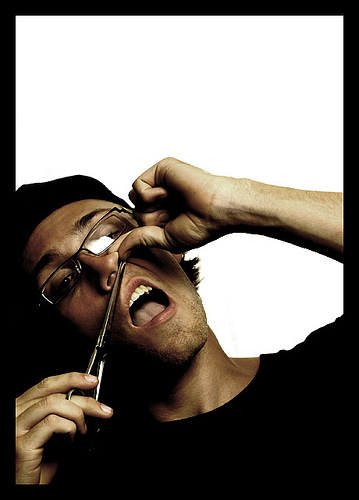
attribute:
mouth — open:
[115, 263, 156, 318]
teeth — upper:
[119, 282, 147, 303]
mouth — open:
[119, 273, 176, 329]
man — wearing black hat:
[16, 157, 344, 483]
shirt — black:
[48, 315, 344, 490]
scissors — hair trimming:
[76, 261, 124, 413]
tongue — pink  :
[138, 298, 169, 320]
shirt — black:
[166, 348, 338, 498]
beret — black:
[14, 172, 79, 231]